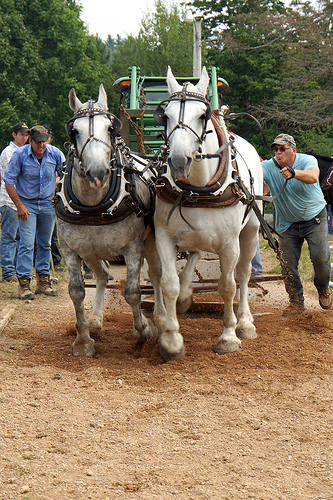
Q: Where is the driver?
A: Behind the white horse.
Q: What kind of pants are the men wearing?
A: Jeans.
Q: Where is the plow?
A: Behind the horses.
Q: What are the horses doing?
A: Pulling a plow.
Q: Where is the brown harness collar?
A: On the white horse.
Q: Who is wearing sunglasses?
A: The driver.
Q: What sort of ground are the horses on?
A: Dirt.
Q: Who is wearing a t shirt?
A: The Driver.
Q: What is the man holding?
A: Strap.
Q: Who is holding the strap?
A: The man.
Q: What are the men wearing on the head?
A: Caps.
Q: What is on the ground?
A: Dirt.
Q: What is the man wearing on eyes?
A: Sunglasses.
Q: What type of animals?
A: Horses.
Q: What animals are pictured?
A: Horses.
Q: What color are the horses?
A: White.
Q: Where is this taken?
A: A farm.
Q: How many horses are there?
A: Two.